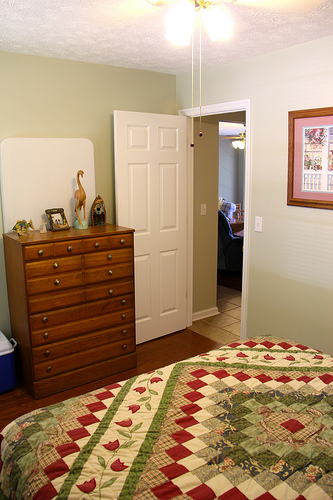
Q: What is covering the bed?
A: A quilt.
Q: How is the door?
A: Open.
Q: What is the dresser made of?
A: Wood.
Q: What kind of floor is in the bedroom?
A: Wooden floor.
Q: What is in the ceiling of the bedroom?
A: A ceiling fan.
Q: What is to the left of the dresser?
A: A cooler.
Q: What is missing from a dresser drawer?
A: A knob.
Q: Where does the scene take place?
A: In a bedroom.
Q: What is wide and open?
A: Door.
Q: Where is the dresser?
A: Against a wall.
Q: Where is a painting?
A: On the wall.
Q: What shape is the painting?
A: Rectangle.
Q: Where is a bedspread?
A: On the bed.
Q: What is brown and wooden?
A: The floor in the bedroom.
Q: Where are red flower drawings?
A: On the quilt.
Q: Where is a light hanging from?
A: Ceiling.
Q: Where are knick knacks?
A: On top of the dresser.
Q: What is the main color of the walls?
A: White.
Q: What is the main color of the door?
A: White.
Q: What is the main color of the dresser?
A: Brown.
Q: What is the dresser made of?
A: Wood.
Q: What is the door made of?
A: Wood.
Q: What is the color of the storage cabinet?
A: Brown.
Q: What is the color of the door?
A: White.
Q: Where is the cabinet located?
A: Near the door.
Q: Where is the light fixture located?
A: On the ceiling.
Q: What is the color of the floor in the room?
A: Brown.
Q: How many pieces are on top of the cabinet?
A: Five.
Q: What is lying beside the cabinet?
A: A cooler.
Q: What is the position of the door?
A: Open.